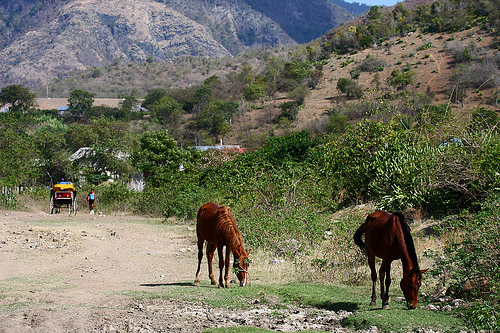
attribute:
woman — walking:
[87, 187, 95, 212]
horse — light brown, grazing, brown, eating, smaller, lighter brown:
[195, 201, 255, 284]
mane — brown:
[218, 206, 248, 258]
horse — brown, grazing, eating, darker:
[353, 209, 429, 309]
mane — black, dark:
[393, 210, 421, 277]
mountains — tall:
[0, 1, 376, 97]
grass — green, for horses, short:
[216, 281, 464, 332]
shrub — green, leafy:
[339, 79, 361, 101]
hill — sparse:
[137, 0, 499, 311]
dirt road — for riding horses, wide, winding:
[2, 202, 283, 332]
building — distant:
[0, 97, 151, 115]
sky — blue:
[346, 1, 400, 8]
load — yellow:
[54, 184, 74, 191]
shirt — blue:
[90, 193, 95, 200]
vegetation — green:
[133, 118, 500, 312]